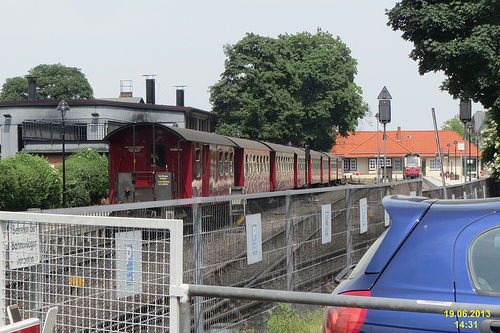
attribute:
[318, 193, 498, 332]
car — blue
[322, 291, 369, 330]
tail light — red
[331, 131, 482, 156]
roof — orange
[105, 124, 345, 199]
train — red, passing through, carrying passengers, going to station, bringing people home, taking people to wor, traveling, running, run by city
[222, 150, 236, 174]
window — small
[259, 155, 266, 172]
window — small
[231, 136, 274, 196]
car — red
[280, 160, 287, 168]
window — small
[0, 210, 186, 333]
fence — white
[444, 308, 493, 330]
numbers — yellow